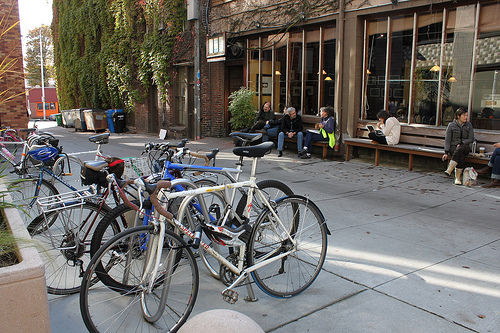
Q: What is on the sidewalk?
A: Bikes.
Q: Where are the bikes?
A: Sidewalk.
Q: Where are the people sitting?
A: Benches.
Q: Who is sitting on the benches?
A: Men and women.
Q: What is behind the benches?
A: Windows.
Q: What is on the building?
A: Windows.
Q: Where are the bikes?
A: In the racks.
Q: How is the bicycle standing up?
A: In the bike rack.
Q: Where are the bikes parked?
A: On the sidewalk.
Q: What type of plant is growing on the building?
A: Vines.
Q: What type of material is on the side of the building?
A: Glass windows.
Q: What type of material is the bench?
A: Wood.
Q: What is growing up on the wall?
A: Ivy.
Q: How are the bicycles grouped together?
A: Parked in rack.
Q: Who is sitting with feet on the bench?
A: The woman in white.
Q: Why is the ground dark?
A: Shade.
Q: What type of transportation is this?
A: Bicycles.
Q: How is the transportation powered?
A: Pedaling.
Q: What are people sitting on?
A: Benches.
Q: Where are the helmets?
A: On the bikes.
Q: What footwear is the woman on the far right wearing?
A: Boots.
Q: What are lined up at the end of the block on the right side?
A: Trash cans.